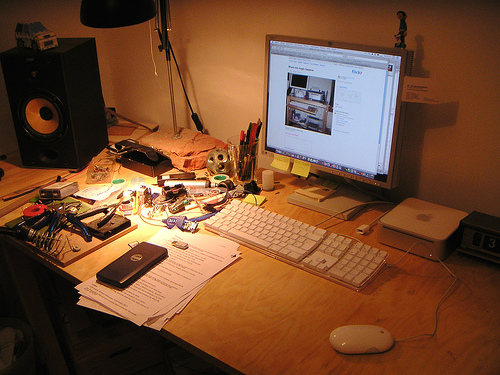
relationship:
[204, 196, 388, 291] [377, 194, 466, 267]
computer keyboard of computer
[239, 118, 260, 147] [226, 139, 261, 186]
pencils in glass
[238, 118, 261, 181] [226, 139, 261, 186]
pencils pens in glass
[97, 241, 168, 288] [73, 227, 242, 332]
phone on pile of papers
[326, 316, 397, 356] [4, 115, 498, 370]
mouse on a desk